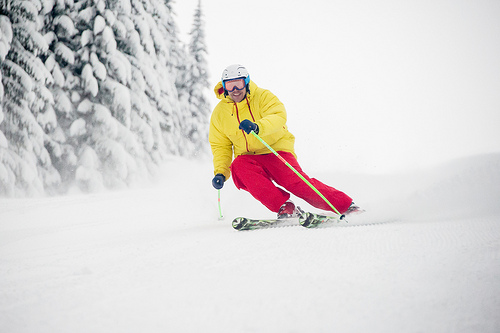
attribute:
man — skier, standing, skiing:
[204, 59, 386, 233]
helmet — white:
[215, 62, 261, 98]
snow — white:
[2, 147, 499, 331]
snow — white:
[26, 19, 52, 56]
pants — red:
[229, 150, 355, 221]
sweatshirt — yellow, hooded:
[205, 77, 304, 182]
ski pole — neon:
[251, 130, 352, 227]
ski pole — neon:
[211, 177, 226, 230]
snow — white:
[61, 3, 148, 197]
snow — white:
[125, 2, 188, 181]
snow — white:
[183, 1, 222, 171]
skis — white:
[228, 210, 377, 238]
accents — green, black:
[236, 213, 332, 230]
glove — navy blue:
[235, 117, 263, 140]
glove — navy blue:
[209, 172, 231, 193]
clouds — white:
[208, 2, 500, 59]